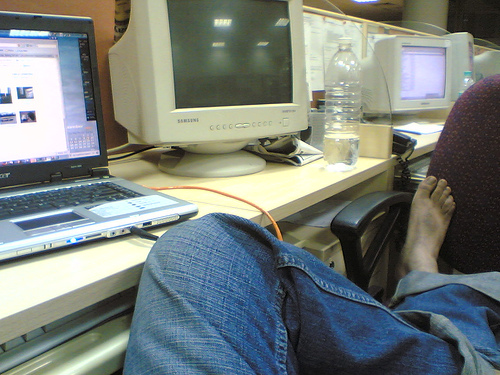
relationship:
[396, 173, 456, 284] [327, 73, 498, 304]
barefoot on chair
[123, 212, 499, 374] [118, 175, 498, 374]
blue jeans on person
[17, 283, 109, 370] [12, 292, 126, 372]
keyboard on shelf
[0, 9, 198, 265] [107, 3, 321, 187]
computer on desk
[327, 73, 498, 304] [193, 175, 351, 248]
chair in front of desk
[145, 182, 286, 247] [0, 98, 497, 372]
orange cable on desk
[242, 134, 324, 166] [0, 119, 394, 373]
folded papers on desk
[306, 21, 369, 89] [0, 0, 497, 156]
papers on wall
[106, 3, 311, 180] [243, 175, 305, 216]
computer monitor on desk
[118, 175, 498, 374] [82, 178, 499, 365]
person wearing jeans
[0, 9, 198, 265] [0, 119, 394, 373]
computer on desk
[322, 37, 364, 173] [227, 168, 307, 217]
bottle on desk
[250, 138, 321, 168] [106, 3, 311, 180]
folded papers next to computer monitor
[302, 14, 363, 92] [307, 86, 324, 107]
papers tacked on cork board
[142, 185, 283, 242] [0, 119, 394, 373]
orange cable on desk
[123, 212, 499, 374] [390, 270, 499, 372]
blue jeans with cuffs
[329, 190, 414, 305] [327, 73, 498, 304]
handle of chair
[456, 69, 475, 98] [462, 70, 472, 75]
bottle with cap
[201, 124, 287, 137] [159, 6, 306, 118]
buttons on front of monitor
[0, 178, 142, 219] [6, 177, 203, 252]
keys on key pad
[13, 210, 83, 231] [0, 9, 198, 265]
trackpad on computer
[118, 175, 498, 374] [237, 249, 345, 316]
person wearing jeans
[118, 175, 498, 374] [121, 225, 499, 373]
person wearing blue jeans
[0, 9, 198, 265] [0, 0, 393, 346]
computer on desk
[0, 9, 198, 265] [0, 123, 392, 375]
computer on desk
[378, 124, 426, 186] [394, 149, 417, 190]
phone with cord